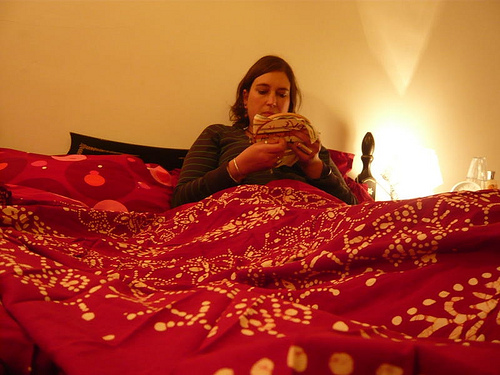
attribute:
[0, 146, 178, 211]
pillow — red, black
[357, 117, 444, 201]
light — bright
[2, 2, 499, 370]
room — dim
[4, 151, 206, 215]
pillow — partially hidden, bed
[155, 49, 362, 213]
woman — knitting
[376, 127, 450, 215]
light — on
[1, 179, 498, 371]
sheet — big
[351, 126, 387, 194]
bed post — wood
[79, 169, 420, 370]
blankets — yellow, red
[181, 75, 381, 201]
lady — sewing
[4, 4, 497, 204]
wall — cream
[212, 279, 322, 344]
design — yellow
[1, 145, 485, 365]
cover — red, spotted, bed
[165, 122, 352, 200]
sweater — stripped